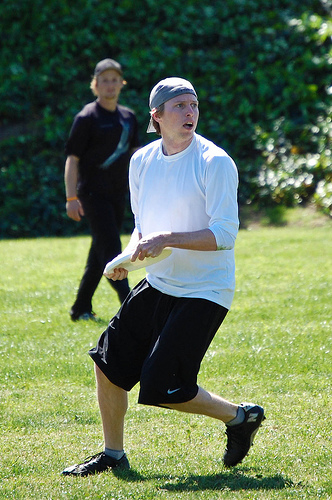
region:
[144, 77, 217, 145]
a hipster wearing backwards baseball cap.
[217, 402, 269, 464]
a black shoe on a foot.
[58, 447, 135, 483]
a black shoe on a right foot.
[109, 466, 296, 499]
shadows cast by shoes.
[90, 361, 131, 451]
a male human shin.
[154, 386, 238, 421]
a pale leg.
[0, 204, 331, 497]
a field of green grass.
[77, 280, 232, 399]
a pair of black shorts.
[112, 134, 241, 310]
a man in a white shirt.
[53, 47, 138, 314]
a boy dressed in black.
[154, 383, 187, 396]
Nike swoosh on the shorts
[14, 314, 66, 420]
Green grass of the park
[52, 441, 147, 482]
Shoes of the frisbee player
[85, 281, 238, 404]
Shorts of the frisbee player that are black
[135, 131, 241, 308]
white shirt of the frisbee player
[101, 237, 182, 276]
White frisbee that they are using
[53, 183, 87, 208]
Orange wrist band that the black shirted player is wearing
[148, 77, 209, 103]
hat of the white shirt frisbee player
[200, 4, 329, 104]
Tree foilage in the park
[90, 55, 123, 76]
hat of the black shirt player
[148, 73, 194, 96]
Man wearing grey hat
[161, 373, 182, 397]
White nike sign on shorts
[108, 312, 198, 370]
Man wearing black shorts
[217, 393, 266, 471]
Man wearing black sneakers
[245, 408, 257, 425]
New balance sign on sneakers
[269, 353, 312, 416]
Green grass in field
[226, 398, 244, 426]
Man wearing grey socks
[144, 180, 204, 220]
Man wearing white shirt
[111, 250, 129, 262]
eight inch white frisby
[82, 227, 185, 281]
White frisby in mans hands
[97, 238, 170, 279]
what plastic frisbee being held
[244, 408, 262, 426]
white letter on side of tennis shoe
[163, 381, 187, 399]
company logo on leg of shorts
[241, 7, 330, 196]
thick hedges with green leaves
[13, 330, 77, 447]
field covered in green grass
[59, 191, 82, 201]
orange wristband on man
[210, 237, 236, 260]
green grass stain on elbow of shirt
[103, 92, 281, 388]
man getting ready to throw frisbee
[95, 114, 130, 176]
design on front of shirt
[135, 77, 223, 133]
grey backwards ball cap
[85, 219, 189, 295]
man is playing Frisbee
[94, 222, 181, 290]
two hands holding a Frisbee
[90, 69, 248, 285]
man is looking to the right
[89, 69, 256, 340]
man wearing a long sleeve shirt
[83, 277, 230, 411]
blue pants of brand Nike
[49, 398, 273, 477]
a pair of black shoes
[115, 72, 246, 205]
man wears a blue cap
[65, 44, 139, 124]
person on back of player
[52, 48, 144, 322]
man wearing black cloths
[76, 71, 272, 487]
man in position to throw a Frisbee